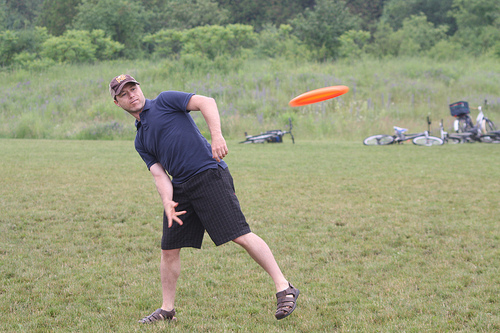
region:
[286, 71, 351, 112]
orange frisbee in air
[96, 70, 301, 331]
man in blue shirt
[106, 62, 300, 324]
man wearing blue shirt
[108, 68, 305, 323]
man in black shorts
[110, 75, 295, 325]
man wearing black shorts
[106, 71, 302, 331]
man in brown shoes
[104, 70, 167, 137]
man in brown hat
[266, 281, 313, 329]
left foot on man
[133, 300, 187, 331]
right foot on man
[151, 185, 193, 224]
right hand on man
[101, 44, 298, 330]
A Man is playing the frisbee game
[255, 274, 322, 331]
the shoes are brown in color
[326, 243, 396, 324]
the floor has grasses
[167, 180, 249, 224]
the pants rae black incolor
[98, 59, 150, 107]
the cape is brown in color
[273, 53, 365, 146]
the frisbe is in air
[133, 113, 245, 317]
ma is dressed in a short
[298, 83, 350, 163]
frisbee is orange in color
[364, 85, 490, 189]
the bicycles are beside the field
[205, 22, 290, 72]
trees are at the background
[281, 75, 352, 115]
A frisbee in the air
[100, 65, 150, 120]
Hat on man's head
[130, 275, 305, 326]
A pair of brown sandals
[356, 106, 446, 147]
A bicycle is on the grass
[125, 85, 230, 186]
A navy blue shirt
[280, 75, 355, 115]
A frisbee is round and orange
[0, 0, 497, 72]
Green trees in the background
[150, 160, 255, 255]
A pair of black shorts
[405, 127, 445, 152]
A round bicycle wheel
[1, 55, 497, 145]
The grass is very long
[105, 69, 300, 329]
Slanted man on one foot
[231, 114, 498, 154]
Bicycles laying on the grass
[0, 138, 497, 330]
Field of short grass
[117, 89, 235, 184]
Dark blue sleeveless shirt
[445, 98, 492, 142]
Bicycle with a blue box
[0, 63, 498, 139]
Area with tall unkempt grass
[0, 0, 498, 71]
Area of thick bush cover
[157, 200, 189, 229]
Straight spread out fingers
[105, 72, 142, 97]
Brown cap with a branding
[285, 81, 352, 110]
Orange tenniquoit in the air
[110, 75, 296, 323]
A man throwing frisbee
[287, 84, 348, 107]
An orange frisbee in air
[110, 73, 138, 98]
Brown cap on the man's head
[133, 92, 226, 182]
A blue polo shirt the man is wearing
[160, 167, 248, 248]
Greyish black shorts the man is wearing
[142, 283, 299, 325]
Brown sandals the man is wearing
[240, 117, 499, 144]
Some bikes kept lying on grass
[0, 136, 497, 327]
The grassy field the man is standing on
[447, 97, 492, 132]
A motorcycle standing on grass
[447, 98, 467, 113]
A carrier box behind the bike seat